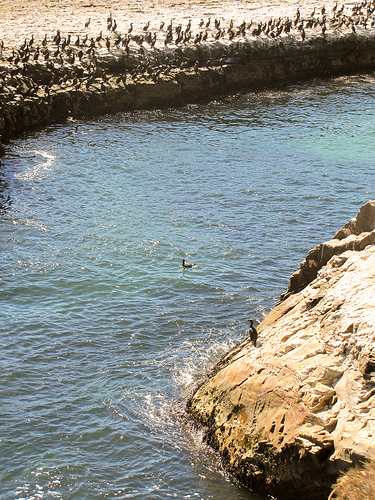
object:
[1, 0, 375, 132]
ledge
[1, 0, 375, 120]
rock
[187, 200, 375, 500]
rocks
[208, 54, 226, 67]
duck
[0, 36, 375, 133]
cliff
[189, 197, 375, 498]
ledge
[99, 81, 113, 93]
birds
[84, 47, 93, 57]
bird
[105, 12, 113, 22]
bird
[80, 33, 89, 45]
bird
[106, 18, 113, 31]
bird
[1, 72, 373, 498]
water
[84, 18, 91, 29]
bird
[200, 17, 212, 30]
bird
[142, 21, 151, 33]
bird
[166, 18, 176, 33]
bird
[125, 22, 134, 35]
bird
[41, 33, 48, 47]
bird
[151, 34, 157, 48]
bird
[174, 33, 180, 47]
bird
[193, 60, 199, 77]
birds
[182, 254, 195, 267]
bird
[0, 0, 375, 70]
beach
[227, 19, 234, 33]
bird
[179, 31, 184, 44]
bird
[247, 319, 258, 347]
bird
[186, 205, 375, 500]
land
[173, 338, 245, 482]
splash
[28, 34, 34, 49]
bird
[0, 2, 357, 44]
grassland